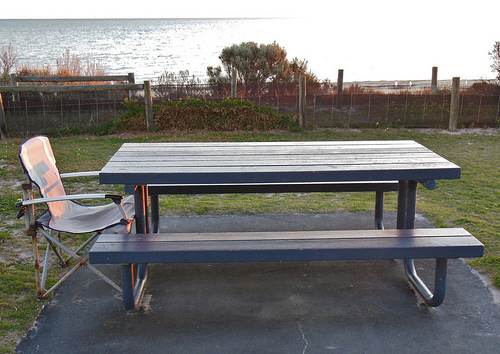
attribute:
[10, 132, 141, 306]
chair — folding, grey, orange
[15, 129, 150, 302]
chair — cloth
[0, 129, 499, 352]
field — grassy, small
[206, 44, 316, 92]
bush — large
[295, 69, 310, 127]
fence post — wooden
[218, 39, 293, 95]
bush — large, full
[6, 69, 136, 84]
crossmember — wooden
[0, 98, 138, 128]
fence — wooden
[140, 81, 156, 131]
post — wooden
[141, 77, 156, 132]
fence post — wooden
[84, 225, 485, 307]
bench — empty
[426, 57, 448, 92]
post — wooden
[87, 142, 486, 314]
picnic table — large, wooden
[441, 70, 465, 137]
fence post — wooden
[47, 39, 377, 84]
ocean — vast